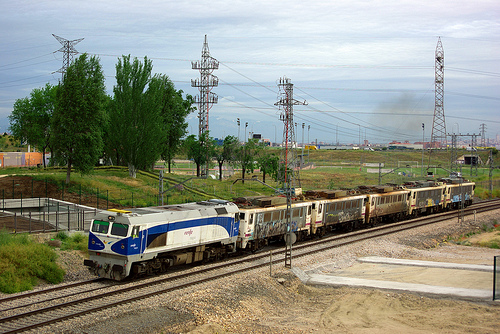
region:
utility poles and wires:
[7, 22, 498, 291]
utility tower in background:
[428, 18, 458, 151]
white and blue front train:
[77, 200, 233, 275]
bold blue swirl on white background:
[120, 210, 242, 255]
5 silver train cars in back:
[240, 183, 485, 244]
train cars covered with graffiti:
[234, 180, 481, 236]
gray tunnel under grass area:
[0, 188, 125, 243]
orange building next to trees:
[3, 147, 55, 170]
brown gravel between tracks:
[0, 193, 498, 331]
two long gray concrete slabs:
[305, 245, 499, 307]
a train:
[62, 195, 187, 283]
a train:
[42, 167, 150, 247]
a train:
[92, 180, 207, 312]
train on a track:
[68, 111, 499, 319]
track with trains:
[32, 95, 490, 319]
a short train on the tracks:
[16, 134, 476, 332]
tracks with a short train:
[50, 134, 490, 325]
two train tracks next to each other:
[22, 257, 113, 331]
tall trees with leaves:
[3, 12, 226, 187]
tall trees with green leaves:
[15, 22, 232, 182]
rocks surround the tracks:
[46, 267, 126, 332]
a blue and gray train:
[80, 157, 294, 331]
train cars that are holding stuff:
[232, 111, 498, 256]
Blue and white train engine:
[76, 189, 275, 288]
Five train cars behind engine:
[34, 170, 484, 272]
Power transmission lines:
[171, 25, 492, 203]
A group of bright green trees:
[3, 50, 197, 177]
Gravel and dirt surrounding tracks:
[108, 254, 303, 308]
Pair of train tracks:
[1, 265, 168, 312]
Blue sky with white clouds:
[88, 5, 430, 145]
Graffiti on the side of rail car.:
[225, 210, 309, 240]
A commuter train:
[91, 159, 483, 256]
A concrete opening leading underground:
[0, 192, 125, 249]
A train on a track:
[60, 160, 481, 277]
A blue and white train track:
[87, 190, 247, 285]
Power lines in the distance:
[45, 27, 494, 169]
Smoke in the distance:
[359, 80, 450, 162]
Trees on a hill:
[15, 42, 171, 178]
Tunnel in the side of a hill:
[2, 153, 132, 265]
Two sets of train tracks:
[28, 258, 230, 332]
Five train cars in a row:
[230, 165, 496, 234]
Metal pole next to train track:
[272, 163, 314, 279]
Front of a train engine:
[80, 198, 143, 285]